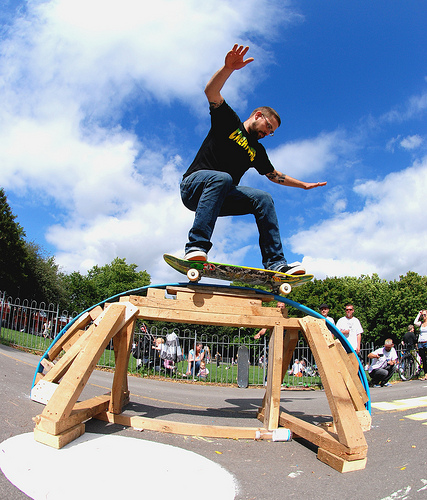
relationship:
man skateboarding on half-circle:
[179, 42, 328, 278] [29, 281, 378, 490]